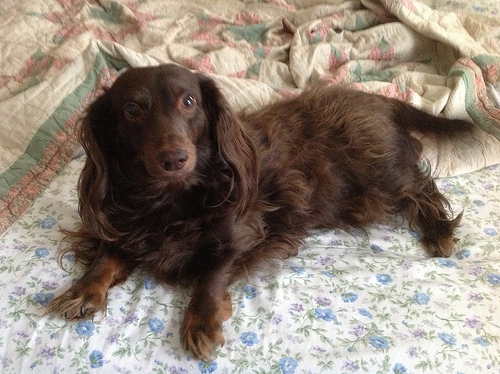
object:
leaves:
[390, 284, 397, 293]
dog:
[52, 64, 474, 361]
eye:
[183, 95, 194, 105]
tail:
[394, 100, 473, 131]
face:
[109, 69, 206, 176]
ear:
[197, 76, 258, 223]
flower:
[90, 351, 102, 370]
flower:
[241, 332, 258, 346]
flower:
[279, 358, 298, 372]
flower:
[315, 308, 335, 321]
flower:
[371, 336, 390, 348]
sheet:
[258, 274, 489, 371]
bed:
[0, 2, 494, 370]